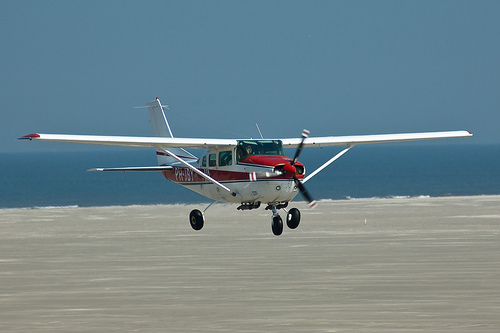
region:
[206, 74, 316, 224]
A red and white plane.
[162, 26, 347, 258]
A red and white plane.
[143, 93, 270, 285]
A red and white plane.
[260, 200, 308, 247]
two black tires of plane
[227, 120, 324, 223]
propeller on a plane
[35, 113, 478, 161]
wide wing of a plane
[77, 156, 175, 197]
side wing of a plane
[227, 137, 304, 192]
pilot in a plane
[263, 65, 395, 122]
patch of blue sky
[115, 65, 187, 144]
white and red tail of plane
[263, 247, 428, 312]
patch of white ice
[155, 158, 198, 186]
white writing on side of plane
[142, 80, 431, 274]
red and white air plane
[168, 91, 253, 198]
A red and white plane.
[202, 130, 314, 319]
A red and white plane.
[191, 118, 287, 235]
A red and white plane.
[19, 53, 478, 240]
red and white airplane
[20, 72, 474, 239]
red and white airplane in flight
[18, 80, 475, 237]
airborne red and white airplane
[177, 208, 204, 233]
black tire of red and white airplane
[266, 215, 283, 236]
black tire of red and white airplane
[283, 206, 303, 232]
black tire of red and white airplane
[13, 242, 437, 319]
gray calm water below airplane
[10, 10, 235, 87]
blue sky without clouds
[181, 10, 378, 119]
blue sky without clouds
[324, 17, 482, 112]
blue sky without clouds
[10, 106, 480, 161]
The wingspan of the plane.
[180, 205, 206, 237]
A tire on the plane.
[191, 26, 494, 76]
The sky is blue.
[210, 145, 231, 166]
A window on the plane.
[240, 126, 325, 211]
A propeller on the plane.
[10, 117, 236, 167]
A wing on the plane.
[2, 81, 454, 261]
The plane has red, white, and black on it.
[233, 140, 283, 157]
The windshield on the plane.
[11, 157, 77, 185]
The ocean in the background.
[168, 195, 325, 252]
The wheels on the plane.